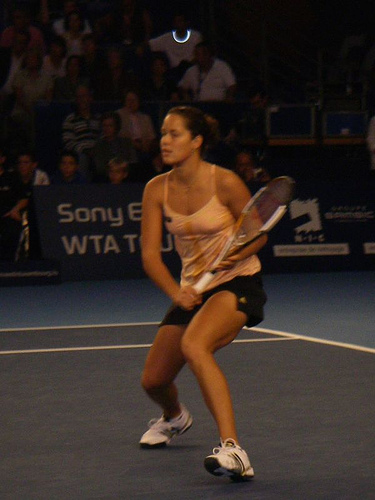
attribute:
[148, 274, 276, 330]
tennis shirt — black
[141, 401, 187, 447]
shoe — white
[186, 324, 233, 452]
leg — left leg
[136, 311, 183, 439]
leg — right  leg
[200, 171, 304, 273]
racket — white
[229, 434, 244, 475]
shoe — white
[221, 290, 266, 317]
skirt — black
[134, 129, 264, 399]
player — light skinned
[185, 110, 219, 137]
hair — short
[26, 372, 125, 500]
pitch — tarmacked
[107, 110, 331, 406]
woman — playing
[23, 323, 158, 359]
line — white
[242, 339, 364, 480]
court — dark blue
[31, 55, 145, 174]
people — background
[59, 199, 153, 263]
words — white